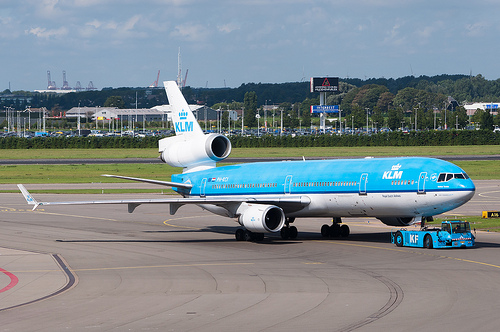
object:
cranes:
[44, 68, 58, 90]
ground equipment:
[388, 218, 475, 249]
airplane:
[15, 77, 476, 242]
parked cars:
[5, 127, 40, 139]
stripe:
[0, 245, 74, 311]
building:
[91, 108, 166, 130]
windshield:
[438, 172, 448, 180]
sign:
[310, 75, 339, 94]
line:
[446, 256, 500, 269]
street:
[0, 180, 500, 331]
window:
[317, 182, 320, 188]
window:
[322, 181, 325, 188]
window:
[332, 181, 339, 186]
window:
[337, 182, 340, 186]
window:
[349, 181, 352, 185]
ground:
[0, 144, 500, 330]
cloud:
[31, 0, 71, 16]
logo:
[381, 168, 403, 180]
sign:
[307, 103, 343, 115]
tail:
[161, 80, 219, 174]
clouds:
[126, 14, 141, 27]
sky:
[0, 0, 500, 92]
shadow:
[53, 222, 396, 246]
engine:
[236, 197, 288, 235]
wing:
[16, 183, 311, 211]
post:
[319, 90, 326, 131]